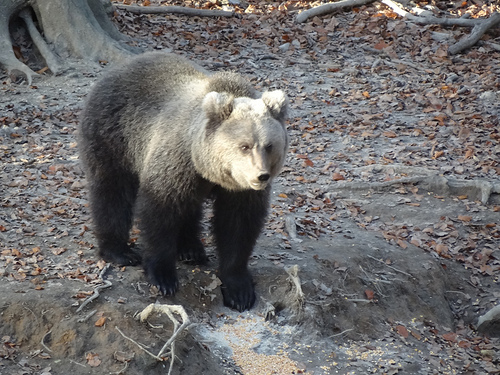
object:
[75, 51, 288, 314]
bear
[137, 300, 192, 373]
stick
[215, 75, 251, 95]
fur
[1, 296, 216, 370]
ground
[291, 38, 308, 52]
leaves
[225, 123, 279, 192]
face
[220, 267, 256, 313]
paw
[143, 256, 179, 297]
paw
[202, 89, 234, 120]
ear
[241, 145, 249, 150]
eye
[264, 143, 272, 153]
eye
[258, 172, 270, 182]
nose